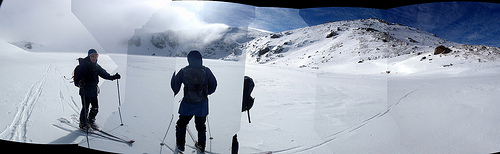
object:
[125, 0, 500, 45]
sky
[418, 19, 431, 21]
clouds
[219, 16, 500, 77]
hill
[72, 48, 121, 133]
man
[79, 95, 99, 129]
pants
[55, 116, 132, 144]
skis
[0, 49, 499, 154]
snow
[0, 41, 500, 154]
sidewalk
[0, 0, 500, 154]
picture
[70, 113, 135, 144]
skis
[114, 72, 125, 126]
poles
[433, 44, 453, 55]
rock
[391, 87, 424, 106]
tracks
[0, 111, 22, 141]
snow tracks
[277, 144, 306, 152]
snow tracks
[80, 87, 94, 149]
ski poles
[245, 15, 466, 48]
snow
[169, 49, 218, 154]
man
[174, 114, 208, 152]
black pants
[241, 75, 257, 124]
back pack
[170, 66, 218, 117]
jacket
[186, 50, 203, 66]
hood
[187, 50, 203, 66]
head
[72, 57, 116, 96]
coat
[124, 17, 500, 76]
mountain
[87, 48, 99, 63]
head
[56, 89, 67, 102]
tracks